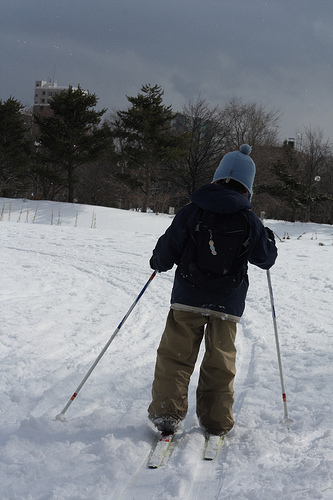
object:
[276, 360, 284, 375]
part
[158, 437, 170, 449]
part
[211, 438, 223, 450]
part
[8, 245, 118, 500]
ground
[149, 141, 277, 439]
person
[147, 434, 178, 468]
skis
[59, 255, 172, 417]
poles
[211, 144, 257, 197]
hat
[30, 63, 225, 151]
building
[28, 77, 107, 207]
trees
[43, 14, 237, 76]
sky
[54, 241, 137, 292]
tracks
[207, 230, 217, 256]
hooker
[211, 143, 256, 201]
head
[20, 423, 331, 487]
snow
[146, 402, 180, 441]
feet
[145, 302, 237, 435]
pants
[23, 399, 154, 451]
shadow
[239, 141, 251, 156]
tip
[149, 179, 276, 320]
jacket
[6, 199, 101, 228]
fence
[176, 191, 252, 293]
backpack